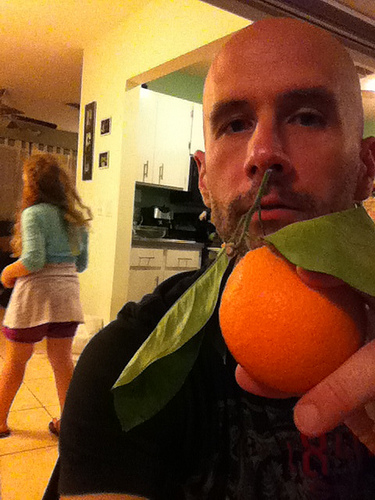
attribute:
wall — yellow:
[76, 6, 263, 351]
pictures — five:
[78, 93, 120, 189]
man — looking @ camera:
[39, 10, 374, 499]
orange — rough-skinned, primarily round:
[219, 239, 372, 385]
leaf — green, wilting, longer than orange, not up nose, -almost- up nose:
[103, 157, 277, 439]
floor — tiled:
[0, 308, 89, 498]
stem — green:
[228, 161, 279, 252]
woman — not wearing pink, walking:
[1, 145, 92, 459]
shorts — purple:
[2, 313, 83, 347]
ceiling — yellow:
[1, 0, 186, 105]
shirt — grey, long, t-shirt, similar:
[2, 254, 93, 332]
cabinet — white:
[139, 87, 186, 189]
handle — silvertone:
[155, 160, 168, 184]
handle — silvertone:
[140, 159, 151, 182]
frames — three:
[85, 102, 109, 179]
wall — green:
[144, 68, 374, 143]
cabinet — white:
[188, 101, 207, 160]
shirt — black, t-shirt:
[53, 253, 372, 500]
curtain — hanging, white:
[0, 138, 77, 252]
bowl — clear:
[133, 222, 172, 238]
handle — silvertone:
[152, 274, 161, 290]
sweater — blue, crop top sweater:
[13, 203, 93, 272]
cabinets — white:
[131, 86, 222, 308]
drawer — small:
[130, 247, 164, 267]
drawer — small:
[166, 250, 198, 270]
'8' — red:
[298, 426, 334, 482]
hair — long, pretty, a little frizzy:
[7, 146, 98, 261]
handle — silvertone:
[134, 254, 160, 265]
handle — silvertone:
[173, 256, 194, 265]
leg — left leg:
[2, 335, 39, 439]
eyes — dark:
[213, 104, 333, 146]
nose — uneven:
[241, 99, 299, 181]